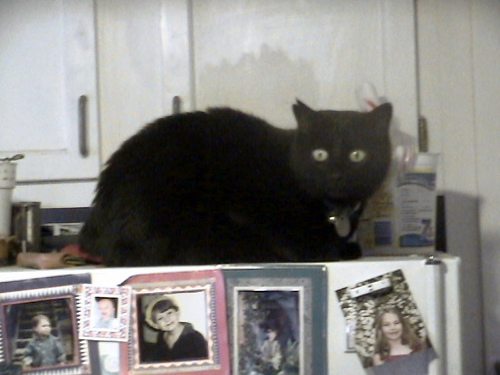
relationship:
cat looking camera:
[74, 90, 397, 257] [161, 77, 443, 363]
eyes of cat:
[309, 145, 366, 163] [74, 90, 397, 257]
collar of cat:
[327, 207, 353, 236] [74, 90, 397, 257]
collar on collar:
[327, 207, 353, 236] [327, 207, 353, 236]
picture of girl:
[330, 257, 442, 372] [367, 299, 440, 370]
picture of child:
[114, 270, 230, 375] [147, 298, 199, 353]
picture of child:
[96, 270, 231, 373] [144, 293, 206, 354]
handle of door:
[69, 86, 100, 156] [10, 5, 110, 185]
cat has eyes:
[74, 90, 397, 257] [310, 146, 371, 172]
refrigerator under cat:
[4, 252, 483, 372] [74, 90, 397, 257]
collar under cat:
[327, 207, 370, 236] [74, 90, 397, 257]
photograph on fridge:
[6, 261, 444, 369] [3, 257, 481, 370]